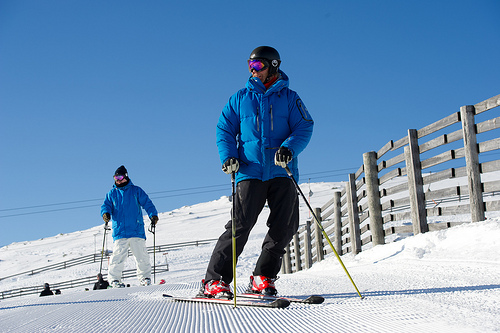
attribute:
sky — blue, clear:
[3, 1, 499, 241]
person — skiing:
[200, 44, 347, 324]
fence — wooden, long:
[270, 103, 499, 274]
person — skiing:
[94, 162, 161, 290]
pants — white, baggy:
[105, 233, 159, 287]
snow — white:
[13, 177, 498, 332]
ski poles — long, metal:
[216, 165, 384, 304]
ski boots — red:
[196, 271, 280, 304]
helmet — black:
[253, 46, 286, 76]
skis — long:
[150, 277, 340, 316]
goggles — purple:
[247, 60, 270, 74]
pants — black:
[204, 165, 308, 282]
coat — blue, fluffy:
[215, 67, 314, 184]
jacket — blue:
[100, 180, 164, 238]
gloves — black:
[214, 151, 293, 179]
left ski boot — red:
[196, 266, 241, 301]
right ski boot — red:
[249, 267, 282, 298]